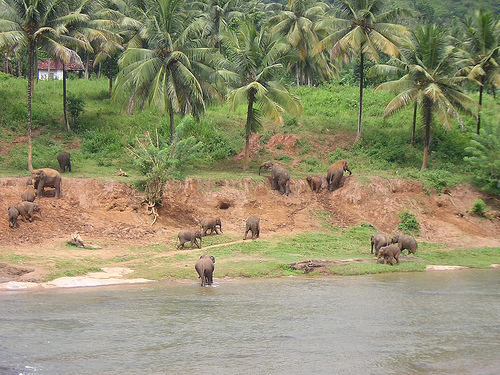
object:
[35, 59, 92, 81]
house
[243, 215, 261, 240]
elephant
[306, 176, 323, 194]
elephant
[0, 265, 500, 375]
lake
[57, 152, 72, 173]
elephants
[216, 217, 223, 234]
head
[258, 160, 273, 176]
head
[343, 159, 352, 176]
head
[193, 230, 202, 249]
head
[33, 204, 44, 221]
head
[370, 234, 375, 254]
head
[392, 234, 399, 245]
head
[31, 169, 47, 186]
head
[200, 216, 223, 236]
elephant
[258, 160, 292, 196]
elephant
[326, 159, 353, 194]
elephant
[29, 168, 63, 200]
elephant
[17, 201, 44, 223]
elephant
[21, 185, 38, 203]
elephant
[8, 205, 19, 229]
elephant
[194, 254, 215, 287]
elephant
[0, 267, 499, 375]
water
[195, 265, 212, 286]
back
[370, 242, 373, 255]
trunk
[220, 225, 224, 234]
trunk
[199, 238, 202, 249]
trunk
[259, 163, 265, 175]
trunk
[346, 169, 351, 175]
trunk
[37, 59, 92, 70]
red roof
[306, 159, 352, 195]
two elephants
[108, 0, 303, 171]
palm trees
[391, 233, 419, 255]
elephant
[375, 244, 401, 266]
elephant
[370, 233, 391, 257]
elephant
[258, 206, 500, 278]
grass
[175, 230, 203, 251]
elephant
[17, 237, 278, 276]
path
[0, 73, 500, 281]
hill